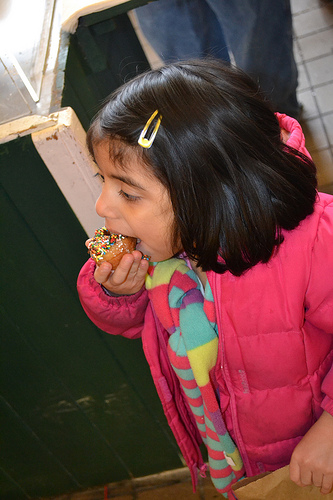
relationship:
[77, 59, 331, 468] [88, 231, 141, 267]
girl eating donut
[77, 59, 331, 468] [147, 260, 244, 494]
girl wearing scarf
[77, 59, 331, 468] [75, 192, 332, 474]
girl wearing coat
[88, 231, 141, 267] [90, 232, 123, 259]
donut has sprinkles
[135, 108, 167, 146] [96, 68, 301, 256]
barette in hair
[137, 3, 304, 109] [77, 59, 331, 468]
person behind girl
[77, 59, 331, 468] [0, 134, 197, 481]
girl next to wall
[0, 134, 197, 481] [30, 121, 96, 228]
wall has trim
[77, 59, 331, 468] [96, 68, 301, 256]
girl has hair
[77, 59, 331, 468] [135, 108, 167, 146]
girl has clip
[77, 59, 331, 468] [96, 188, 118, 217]
girl has nose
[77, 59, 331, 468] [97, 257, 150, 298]
girl has fingers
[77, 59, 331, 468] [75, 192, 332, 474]
girl has jacket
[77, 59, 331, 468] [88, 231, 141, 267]
girl has cup cake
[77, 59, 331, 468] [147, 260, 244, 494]
girl has scarf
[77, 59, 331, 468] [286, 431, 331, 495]
girl has hand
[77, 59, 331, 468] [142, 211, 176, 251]
girl has cheeks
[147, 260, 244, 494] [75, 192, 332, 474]
scarf compliments coat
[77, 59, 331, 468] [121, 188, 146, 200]
girl has eyes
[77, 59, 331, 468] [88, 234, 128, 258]
girl eating pastry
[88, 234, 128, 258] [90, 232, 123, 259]
pastry with sprinkles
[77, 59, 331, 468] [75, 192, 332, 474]
girl has coat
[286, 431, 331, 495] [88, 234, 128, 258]
hand has pastry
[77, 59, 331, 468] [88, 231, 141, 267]
girl eating treat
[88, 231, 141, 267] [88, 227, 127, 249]
treat has candy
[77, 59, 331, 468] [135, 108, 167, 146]
girl has clasp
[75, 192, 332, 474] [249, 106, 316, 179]
coat has hood